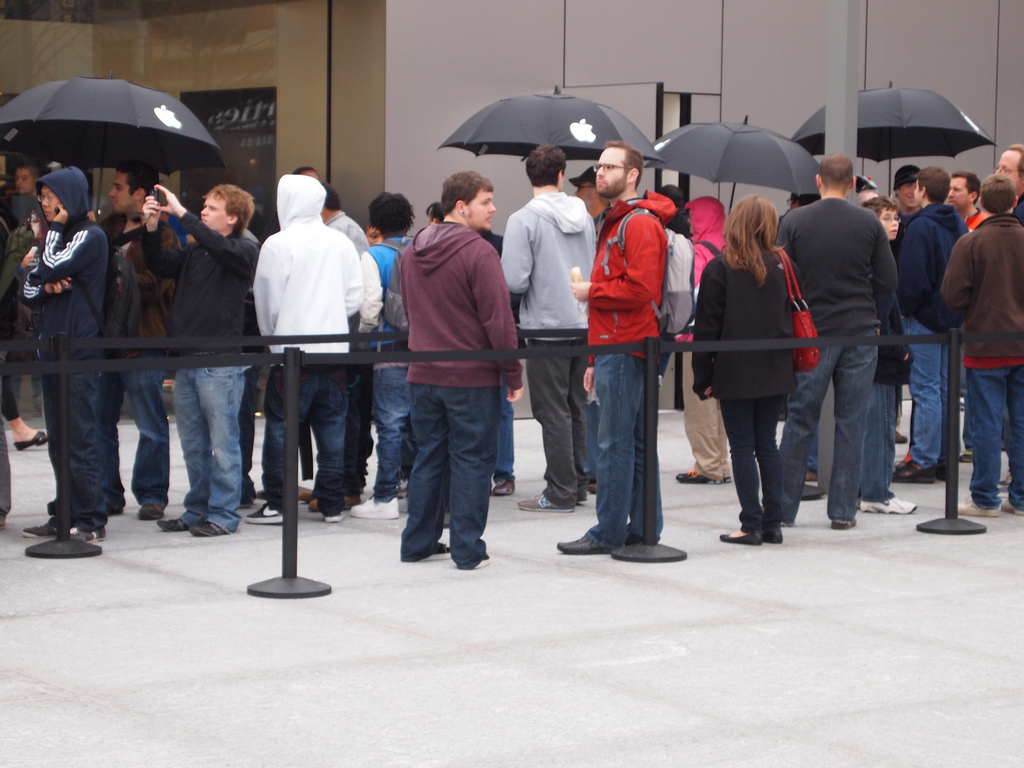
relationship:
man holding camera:
[136, 175, 263, 542] [145, 184, 164, 211]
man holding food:
[555, 139, 667, 554] [566, 262, 587, 290]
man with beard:
[555, 139, 667, 554] [595, 173, 630, 200]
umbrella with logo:
[432, 87, 661, 180] [563, 111, 599, 146]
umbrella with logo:
[8, 74, 222, 174] [149, 96, 186, 129]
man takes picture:
[139, 183, 258, 539] [17, 15, 147, 264]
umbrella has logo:
[438, 85, 666, 162] [563, 111, 599, 146]